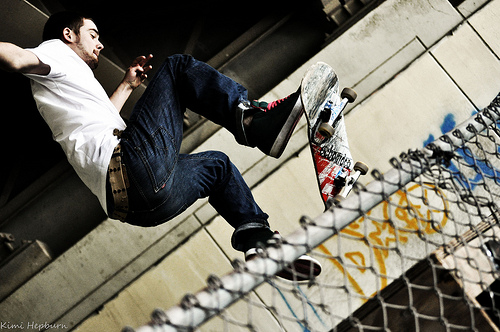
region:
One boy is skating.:
[25, 5, 410, 265]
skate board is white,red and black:
[265, 60, 380, 190]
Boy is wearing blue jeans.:
[130, 110, 170, 195]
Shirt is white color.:
[60, 95, 85, 130]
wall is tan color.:
[375, 55, 440, 105]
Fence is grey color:
[300, 230, 420, 315]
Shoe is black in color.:
[255, 90, 305, 145]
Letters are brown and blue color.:
[275, 150, 485, 265]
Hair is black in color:
[51, 15, 72, 31]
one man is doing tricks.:
[44, 25, 374, 250]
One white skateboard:
[301, 67, 367, 220]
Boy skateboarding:
[6, 7, 365, 282]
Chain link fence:
[217, 165, 493, 320]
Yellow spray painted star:
[363, 217, 408, 259]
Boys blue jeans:
[121, 47, 291, 253]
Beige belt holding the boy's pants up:
[103, 133, 138, 229]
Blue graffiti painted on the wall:
[420, 101, 497, 186]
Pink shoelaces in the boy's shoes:
[254, 82, 299, 114]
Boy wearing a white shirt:
[1, 6, 341, 284]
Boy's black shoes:
[245, 87, 310, 159]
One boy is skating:
[16, 14, 418, 271]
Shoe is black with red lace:
[250, 80, 304, 160]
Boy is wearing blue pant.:
[129, 127, 191, 213]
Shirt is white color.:
[51, 64, 115, 158]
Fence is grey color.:
[348, 203, 457, 295]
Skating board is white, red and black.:
[300, 63, 382, 194]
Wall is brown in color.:
[380, 58, 467, 107]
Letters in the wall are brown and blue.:
[304, 141, 496, 256]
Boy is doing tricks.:
[32, 25, 358, 242]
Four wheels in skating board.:
[315, 86, 382, 213]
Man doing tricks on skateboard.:
[11, 8, 376, 280]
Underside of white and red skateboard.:
[296, 56, 366, 212]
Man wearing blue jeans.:
[110, 57, 253, 227]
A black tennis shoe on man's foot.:
[240, 88, 323, 160]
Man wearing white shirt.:
[28, 37, 121, 224]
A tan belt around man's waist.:
[98, 139, 138, 229]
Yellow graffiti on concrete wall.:
[310, 176, 497, 295]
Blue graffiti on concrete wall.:
[419, 114, 498, 194]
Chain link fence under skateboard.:
[283, 149, 498, 324]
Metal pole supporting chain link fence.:
[298, 108, 498, 263]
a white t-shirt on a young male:
[17, 31, 133, 222]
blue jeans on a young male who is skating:
[102, 47, 274, 249]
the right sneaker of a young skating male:
[232, 84, 312, 159]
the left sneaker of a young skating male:
[236, 223, 328, 289]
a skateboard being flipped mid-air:
[290, 56, 382, 220]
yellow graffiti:
[289, 168, 466, 307]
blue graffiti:
[414, 103, 499, 194]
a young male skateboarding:
[1, 4, 326, 285]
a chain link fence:
[114, 89, 499, 329]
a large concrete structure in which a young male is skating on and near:
[0, 0, 499, 330]